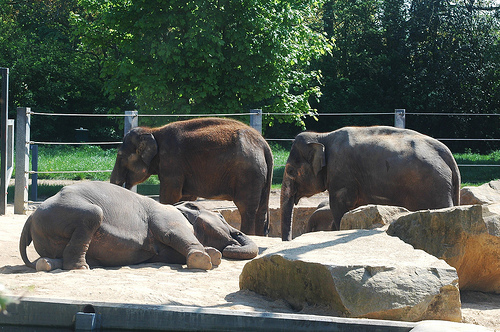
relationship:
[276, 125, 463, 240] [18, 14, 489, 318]
animal are in zoo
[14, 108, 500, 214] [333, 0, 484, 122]
fence in front of tree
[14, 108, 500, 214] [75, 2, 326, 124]
fence in front of tree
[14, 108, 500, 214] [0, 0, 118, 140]
fence in front of tree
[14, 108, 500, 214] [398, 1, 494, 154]
fence in front of tree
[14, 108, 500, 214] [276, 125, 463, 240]
fence behind animal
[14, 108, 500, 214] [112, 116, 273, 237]
fence behind animal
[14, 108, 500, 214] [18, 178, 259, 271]
fence behind animal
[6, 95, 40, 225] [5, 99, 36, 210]
brick in fence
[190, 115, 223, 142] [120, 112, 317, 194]
hair on elephant